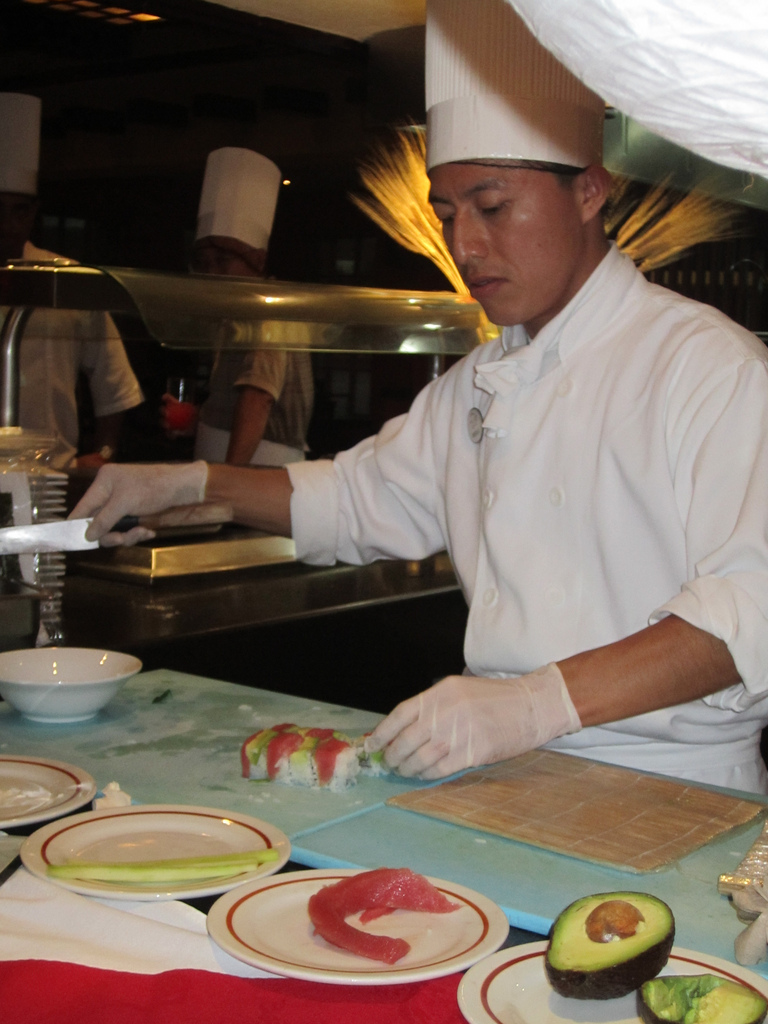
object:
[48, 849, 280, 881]
cucumber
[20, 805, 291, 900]
plate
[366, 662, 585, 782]
glove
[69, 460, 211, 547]
glove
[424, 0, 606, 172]
hat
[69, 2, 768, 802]
chef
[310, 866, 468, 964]
food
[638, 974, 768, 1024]
food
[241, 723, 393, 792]
food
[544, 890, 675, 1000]
avocado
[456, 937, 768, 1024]
plate